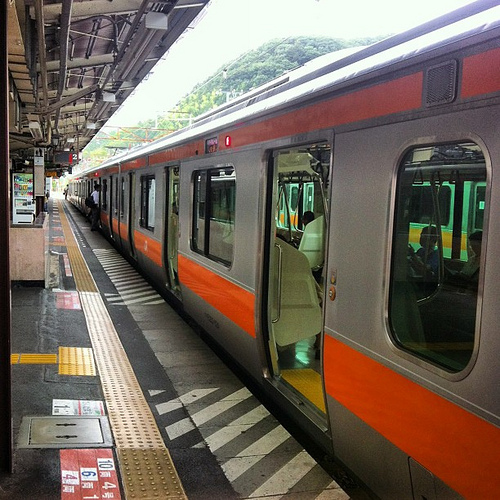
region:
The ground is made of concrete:
[113, 282, 225, 498]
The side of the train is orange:
[174, 248, 252, 333]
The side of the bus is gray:
[66, 122, 499, 432]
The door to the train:
[249, 133, 335, 445]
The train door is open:
[244, 128, 348, 453]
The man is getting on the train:
[83, 178, 111, 237]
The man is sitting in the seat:
[398, 223, 447, 296]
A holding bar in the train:
[414, 175, 449, 320]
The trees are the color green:
[121, 25, 365, 150]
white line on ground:
[146, 386, 166, 397]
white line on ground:
[155, 387, 219, 414]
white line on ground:
[166, 387, 254, 439]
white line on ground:
[191, 402, 268, 457]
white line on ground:
[223, 424, 290, 479]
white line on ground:
[247, 446, 313, 498]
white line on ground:
[108, 288, 158, 305]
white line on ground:
[146, 293, 166, 308]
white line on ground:
[105, 264, 137, 272]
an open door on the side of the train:
[263, 140, 328, 420]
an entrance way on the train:
[262, 139, 329, 416]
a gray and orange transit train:
[67, 1, 497, 498]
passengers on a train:
[294, 209, 481, 288]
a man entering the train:
[82, 180, 104, 232]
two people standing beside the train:
[61, 181, 101, 234]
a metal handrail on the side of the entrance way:
[270, 242, 285, 324]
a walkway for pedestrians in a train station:
[47, 211, 239, 498]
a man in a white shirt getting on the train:
[82, 180, 111, 234]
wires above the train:
[88, 123, 153, 145]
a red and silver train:
[77, 32, 498, 474]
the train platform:
[22, 189, 194, 496]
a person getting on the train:
[87, 186, 102, 216]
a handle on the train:
[271, 241, 285, 327]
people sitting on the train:
[399, 209, 497, 304]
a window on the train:
[397, 146, 473, 361]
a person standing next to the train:
[58, 183, 69, 201]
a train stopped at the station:
[73, 9, 491, 496]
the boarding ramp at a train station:
[43, 215, 249, 496]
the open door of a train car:
[253, 145, 335, 426]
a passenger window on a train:
[389, 143, 483, 378]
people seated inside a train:
[407, 221, 483, 286]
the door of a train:
[161, 165, 183, 298]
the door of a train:
[123, 170, 139, 260]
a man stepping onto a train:
[85, 175, 106, 232]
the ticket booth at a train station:
[12, 148, 53, 288]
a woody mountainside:
[179, 18, 366, 100]